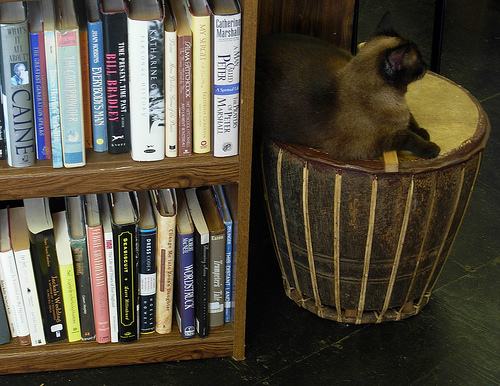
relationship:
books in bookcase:
[0, 1, 240, 348] [7, 17, 285, 364]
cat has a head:
[298, 43, 439, 165] [371, 10, 430, 88]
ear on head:
[373, 11, 395, 36] [346, 10, 429, 92]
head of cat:
[346, 10, 429, 92] [256, 10, 441, 162]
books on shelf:
[7, 7, 258, 178] [9, 149, 263, 200]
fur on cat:
[279, 63, 311, 103] [256, 10, 441, 162]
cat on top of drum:
[252, 32, 440, 161] [262, 45, 480, 325]